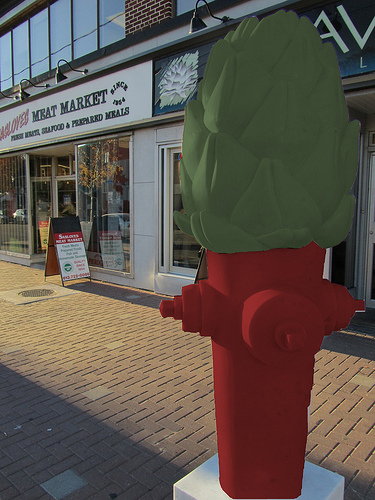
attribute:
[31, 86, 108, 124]
words — meat market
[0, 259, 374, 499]
sidewalk — brick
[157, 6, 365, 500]
hydrant — red, photoshopped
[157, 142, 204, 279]
window — glass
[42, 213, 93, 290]
sign — red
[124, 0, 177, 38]
brick — red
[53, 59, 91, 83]
light — black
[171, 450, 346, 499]
base — white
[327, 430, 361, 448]
brick — tan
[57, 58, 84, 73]
pole — curved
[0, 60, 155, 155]
sign — white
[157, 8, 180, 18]
brick — red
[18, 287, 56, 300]
manhole cover — round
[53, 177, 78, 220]
door — glass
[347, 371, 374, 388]
brick — white